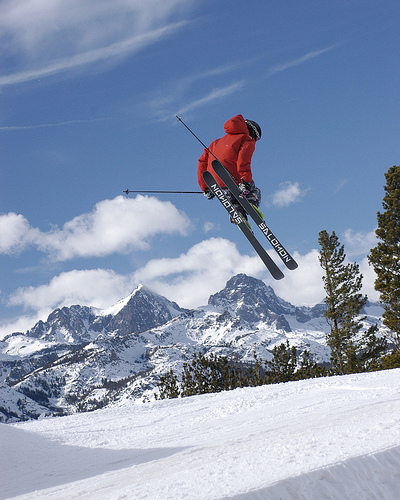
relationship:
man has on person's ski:
[197, 112, 265, 224] [202, 156, 298, 280]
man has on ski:
[197, 112, 265, 224] [211, 158, 297, 268]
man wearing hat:
[197, 112, 265, 224] [245, 119, 261, 139]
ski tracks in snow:
[207, 391, 328, 440] [120, 406, 397, 481]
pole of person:
[118, 181, 204, 201] [186, 111, 271, 225]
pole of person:
[172, 112, 240, 191] [186, 111, 271, 225]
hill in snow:
[0, 277, 400, 420] [125, 475, 172, 496]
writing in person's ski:
[210, 184, 242, 226] [202, 156, 298, 280]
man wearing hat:
[197, 112, 265, 224] [245, 115, 261, 139]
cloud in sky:
[0, 0, 400, 335] [3, 2, 387, 334]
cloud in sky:
[171, 41, 344, 123] [3, 2, 387, 334]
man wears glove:
[197, 112, 265, 224] [237, 181, 253, 200]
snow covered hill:
[5, 367, 399, 499] [0, 277, 400, 420]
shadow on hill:
[0, 406, 220, 499] [113, 285, 190, 338]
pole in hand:
[122, 188, 204, 195] [238, 180, 252, 199]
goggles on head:
[243, 117, 264, 144] [236, 111, 265, 145]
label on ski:
[258, 224, 290, 269] [210, 151, 298, 276]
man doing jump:
[197, 112, 265, 224] [191, 90, 285, 316]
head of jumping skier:
[244, 118, 262, 141] [195, 113, 265, 236]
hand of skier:
[237, 175, 260, 199] [167, 101, 287, 282]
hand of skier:
[238, 180, 252, 199] [173, 111, 282, 231]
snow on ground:
[5, 367, 399, 499] [293, 408, 349, 485]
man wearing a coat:
[197, 112, 265, 224] [196, 115, 256, 198]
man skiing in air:
[193, 112, 265, 224] [4, 10, 398, 332]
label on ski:
[257, 222, 290, 263] [259, 221, 285, 274]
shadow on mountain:
[0, 422, 196, 499] [10, 250, 372, 400]